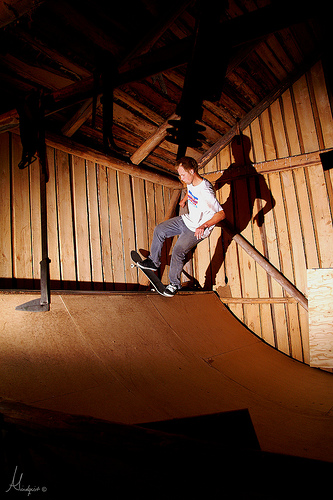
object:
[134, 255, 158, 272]
shoes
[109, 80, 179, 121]
signal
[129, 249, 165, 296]
skateboard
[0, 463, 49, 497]
name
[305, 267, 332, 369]
board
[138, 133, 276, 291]
ceiling shadow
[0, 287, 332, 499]
ramp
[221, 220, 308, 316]
poles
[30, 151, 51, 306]
pole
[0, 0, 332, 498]
building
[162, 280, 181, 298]
sneaker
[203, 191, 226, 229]
arm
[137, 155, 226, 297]
boarder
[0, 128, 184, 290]
wall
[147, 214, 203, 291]
pants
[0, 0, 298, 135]
beam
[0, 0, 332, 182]
ceiling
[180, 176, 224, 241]
shirt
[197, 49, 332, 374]
wall